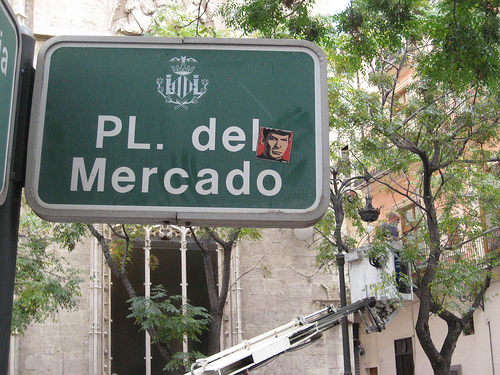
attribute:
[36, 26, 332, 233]
sign — foreign, green 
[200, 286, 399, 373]
construction boom — White , metal 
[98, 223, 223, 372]
doorway — Dark , shadowed 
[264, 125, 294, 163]
sticker — red , black 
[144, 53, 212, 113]
symbol — white 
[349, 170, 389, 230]
bulb holder — black , decorative , iron 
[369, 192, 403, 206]
brick — red 